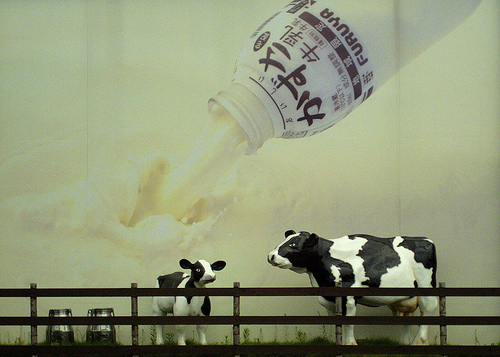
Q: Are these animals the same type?
A: Yes, all the animals are cows.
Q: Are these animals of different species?
A: No, all the animals are cows.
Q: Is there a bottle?
A: Yes, there is a bottle.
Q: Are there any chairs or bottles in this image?
A: Yes, there is a bottle.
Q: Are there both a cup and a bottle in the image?
A: No, there is a bottle but no cups.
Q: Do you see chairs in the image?
A: No, there are no chairs.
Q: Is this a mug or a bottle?
A: This is a bottle.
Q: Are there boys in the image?
A: No, there are no boys.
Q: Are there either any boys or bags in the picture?
A: No, there are no boys or bags.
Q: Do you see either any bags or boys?
A: No, there are no boys or bags.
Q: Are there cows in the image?
A: Yes, there is a cow.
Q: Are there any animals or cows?
A: Yes, there is a cow.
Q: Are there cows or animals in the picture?
A: Yes, there is a cow.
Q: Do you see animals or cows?
A: Yes, there is a cow.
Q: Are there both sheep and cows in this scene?
A: No, there is a cow but no sheep.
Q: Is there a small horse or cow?
A: Yes, there is a small cow.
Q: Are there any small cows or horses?
A: Yes, there is a small cow.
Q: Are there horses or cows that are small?
A: Yes, the cow is small.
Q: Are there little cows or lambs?
A: Yes, there is a little cow.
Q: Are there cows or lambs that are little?
A: Yes, the cow is little.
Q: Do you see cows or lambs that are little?
A: Yes, the cow is little.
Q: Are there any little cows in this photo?
A: Yes, there is a little cow.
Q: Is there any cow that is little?
A: Yes, there is a cow that is little.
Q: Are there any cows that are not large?
A: Yes, there is a little cow.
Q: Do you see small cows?
A: Yes, there is a small cow.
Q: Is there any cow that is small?
A: Yes, there is a cow that is small.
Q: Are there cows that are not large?
A: Yes, there is a small cow.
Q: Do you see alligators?
A: No, there are no alligators.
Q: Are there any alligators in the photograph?
A: No, there are no alligators.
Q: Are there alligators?
A: No, there are no alligators.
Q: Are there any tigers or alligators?
A: No, there are no alligators or tigers.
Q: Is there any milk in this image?
A: Yes, there is milk.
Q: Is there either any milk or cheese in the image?
A: Yes, there is milk.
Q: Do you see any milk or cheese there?
A: Yes, there is milk.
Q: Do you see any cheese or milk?
A: Yes, there is milk.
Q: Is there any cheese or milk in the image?
A: Yes, there is milk.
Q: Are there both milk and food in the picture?
A: No, there is milk but no food.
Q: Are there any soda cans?
A: No, there are no soda cans.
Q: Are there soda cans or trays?
A: No, there are no soda cans or trays.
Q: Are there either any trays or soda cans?
A: No, there are no soda cans or trays.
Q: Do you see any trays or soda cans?
A: No, there are no soda cans or trays.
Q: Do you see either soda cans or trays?
A: No, there are no soda cans or trays.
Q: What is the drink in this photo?
A: The drink is milk.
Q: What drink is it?
A: The drink is milk.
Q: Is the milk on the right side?
A: No, the milk is on the left of the image.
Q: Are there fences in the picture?
A: Yes, there is a fence.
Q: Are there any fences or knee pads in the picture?
A: Yes, there is a fence.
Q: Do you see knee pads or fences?
A: Yes, there is a fence.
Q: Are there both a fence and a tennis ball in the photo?
A: No, there is a fence but no tennis balls.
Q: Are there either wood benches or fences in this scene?
A: Yes, there is a wood fence.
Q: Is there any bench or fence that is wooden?
A: Yes, the fence is wooden.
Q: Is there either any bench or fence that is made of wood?
A: Yes, the fence is made of wood.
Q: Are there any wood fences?
A: Yes, there is a wood fence.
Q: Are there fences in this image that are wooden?
A: Yes, there is a fence that is wooden.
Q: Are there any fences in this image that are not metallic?
A: Yes, there is a wooden fence.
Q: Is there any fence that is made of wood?
A: Yes, there is a fence that is made of wood.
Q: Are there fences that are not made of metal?
A: Yes, there is a fence that is made of wood.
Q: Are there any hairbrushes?
A: No, there are no hairbrushes.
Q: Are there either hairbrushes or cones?
A: No, there are no hairbrushes or cones.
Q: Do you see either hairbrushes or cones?
A: No, there are no hairbrushes or cones.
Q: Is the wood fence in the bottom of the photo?
A: Yes, the fence is in the bottom of the image.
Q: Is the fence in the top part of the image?
A: No, the fence is in the bottom of the image.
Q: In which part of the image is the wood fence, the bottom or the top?
A: The fence is in the bottom of the image.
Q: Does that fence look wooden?
A: Yes, the fence is wooden.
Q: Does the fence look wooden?
A: Yes, the fence is wooden.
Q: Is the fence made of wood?
A: Yes, the fence is made of wood.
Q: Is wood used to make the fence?
A: Yes, the fence is made of wood.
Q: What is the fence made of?
A: The fence is made of wood.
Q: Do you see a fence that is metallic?
A: No, there is a fence but it is wooden.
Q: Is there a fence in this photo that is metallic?
A: No, there is a fence but it is wooden.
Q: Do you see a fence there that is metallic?
A: No, there is a fence but it is wooden.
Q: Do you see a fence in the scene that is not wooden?
A: No, there is a fence but it is wooden.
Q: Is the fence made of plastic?
A: No, the fence is made of wood.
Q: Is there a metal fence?
A: No, there is a fence but it is made of wood.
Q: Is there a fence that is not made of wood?
A: No, there is a fence but it is made of wood.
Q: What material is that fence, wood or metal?
A: The fence is made of wood.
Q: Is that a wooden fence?
A: Yes, that is a wooden fence.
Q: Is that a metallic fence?
A: No, that is a wooden fence.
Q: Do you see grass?
A: Yes, there is grass.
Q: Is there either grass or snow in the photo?
A: Yes, there is grass.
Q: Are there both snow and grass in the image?
A: No, there is grass but no snow.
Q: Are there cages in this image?
A: No, there are no cages.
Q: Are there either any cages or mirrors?
A: No, there are no cages or mirrors.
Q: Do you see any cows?
A: Yes, there is a cow.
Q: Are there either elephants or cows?
A: Yes, there is a cow.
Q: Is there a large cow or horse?
A: Yes, there is a large cow.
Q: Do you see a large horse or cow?
A: Yes, there is a large cow.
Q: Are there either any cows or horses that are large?
A: Yes, the cow is large.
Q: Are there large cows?
A: Yes, there is a large cow.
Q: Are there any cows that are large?
A: Yes, there is a cow that is large.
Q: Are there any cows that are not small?
A: Yes, there is a large cow.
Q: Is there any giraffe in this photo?
A: No, there are no giraffes.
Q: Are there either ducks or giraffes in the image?
A: No, there are no giraffes or ducks.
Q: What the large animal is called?
A: The animal is a cow.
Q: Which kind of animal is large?
A: The animal is a cow.